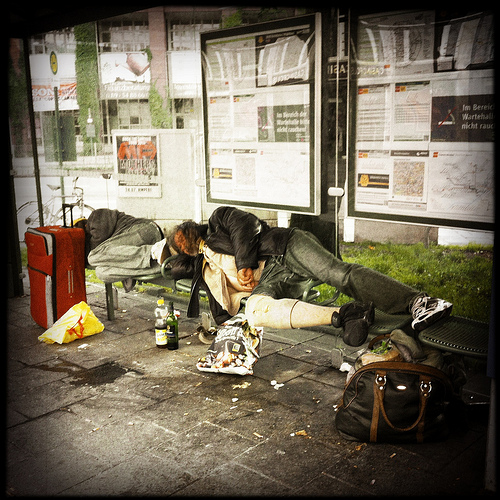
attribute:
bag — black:
[337, 362, 464, 445]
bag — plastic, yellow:
[37, 297, 106, 347]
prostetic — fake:
[246, 294, 337, 329]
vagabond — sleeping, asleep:
[164, 205, 453, 346]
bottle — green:
[167, 298, 181, 350]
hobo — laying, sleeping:
[76, 208, 170, 279]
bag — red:
[27, 225, 88, 331]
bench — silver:
[421, 310, 495, 363]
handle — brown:
[375, 387, 405, 432]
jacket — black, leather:
[197, 205, 295, 268]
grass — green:
[341, 238, 493, 323]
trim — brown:
[370, 384, 380, 440]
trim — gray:
[43, 235, 56, 323]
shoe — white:
[409, 296, 452, 330]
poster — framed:
[199, 29, 324, 210]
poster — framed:
[350, 6, 500, 233]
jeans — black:
[251, 233, 425, 320]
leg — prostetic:
[245, 259, 337, 333]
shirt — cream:
[200, 246, 264, 315]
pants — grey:
[87, 222, 164, 284]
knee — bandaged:
[247, 293, 276, 328]